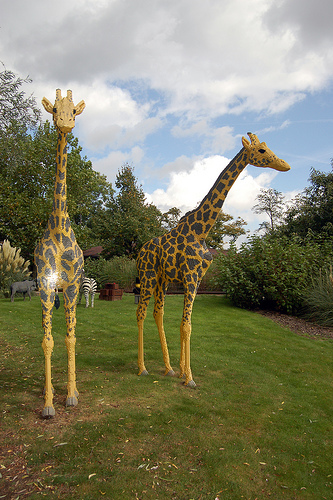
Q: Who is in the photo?
A: No one.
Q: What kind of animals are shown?
A: Giraffe, zebra, hippo.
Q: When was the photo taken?
A: Daytime.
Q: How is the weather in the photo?
A: Fair but cloudy.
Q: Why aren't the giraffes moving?
A: They are statues.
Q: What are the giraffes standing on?
A: Grass.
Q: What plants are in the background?
A: Trees and shrubs.